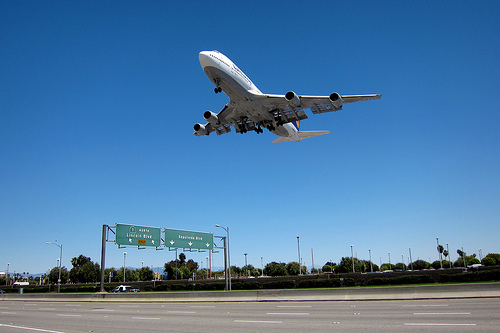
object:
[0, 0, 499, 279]
sky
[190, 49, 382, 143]
plane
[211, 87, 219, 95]
wheels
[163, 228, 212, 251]
signs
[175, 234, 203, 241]
lettering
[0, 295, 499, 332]
street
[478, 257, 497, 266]
bushes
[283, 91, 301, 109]
engine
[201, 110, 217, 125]
engine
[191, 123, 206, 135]
engine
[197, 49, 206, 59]
nose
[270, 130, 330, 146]
tail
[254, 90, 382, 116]
wing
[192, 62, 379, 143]
underside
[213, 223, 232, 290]
light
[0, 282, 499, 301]
barrier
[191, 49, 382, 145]
taken off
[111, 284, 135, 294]
car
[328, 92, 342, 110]
engines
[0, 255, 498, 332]
bottom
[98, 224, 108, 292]
poles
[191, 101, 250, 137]
wings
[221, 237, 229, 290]
poles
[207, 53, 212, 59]
windows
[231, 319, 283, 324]
white lines